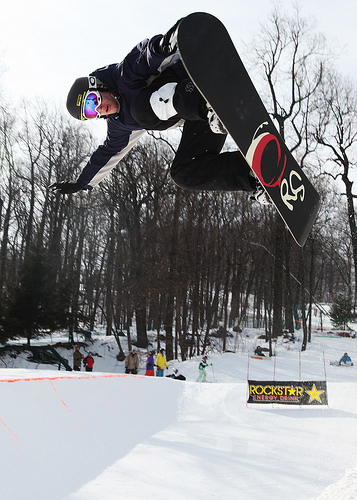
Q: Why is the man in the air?
A: For a snowboarding trick.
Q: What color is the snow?
A: White.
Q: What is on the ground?
A: Snow.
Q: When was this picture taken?
A: Day time.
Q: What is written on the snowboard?
A: RS.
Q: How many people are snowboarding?
A: One.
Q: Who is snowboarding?
A: The man.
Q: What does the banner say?
A: Rockstar Energy Drink.